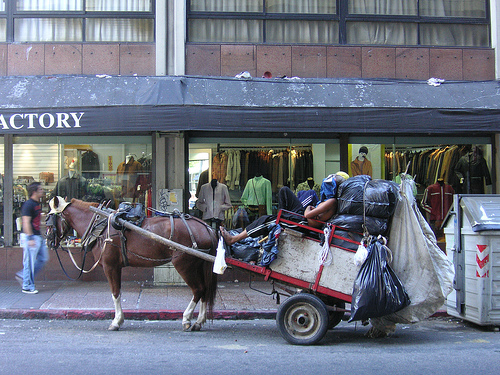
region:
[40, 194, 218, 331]
brown and white horse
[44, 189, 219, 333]
brown horse carrying a wheelbarrow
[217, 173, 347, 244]
man sleeping on a wheelbarrow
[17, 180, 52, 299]
man walking on sidewalk wearing blue t-shirt and blue jeans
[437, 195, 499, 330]
large store in the back big gray garbage can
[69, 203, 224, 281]
reins of a horse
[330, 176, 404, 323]
black bags on a red and white wheelbarrow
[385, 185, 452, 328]
big white bag on wheelbarrow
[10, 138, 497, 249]
a bunch of clothes in the shop window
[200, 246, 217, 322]
large black hairy tail of horse carrying a wheelbarrow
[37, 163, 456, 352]
A horse pulling a white cart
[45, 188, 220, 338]
Brown horse that is wearing gear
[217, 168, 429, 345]
Man resting in two wheel cart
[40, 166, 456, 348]
Horse pulling two wheeled white and red cart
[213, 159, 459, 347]
Man resting on a packed cart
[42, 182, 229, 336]
Brown horse with white stockings stopped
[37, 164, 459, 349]
Horse pulled cart stopped on road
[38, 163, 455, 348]
Horse drawn red and white cart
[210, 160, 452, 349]
Man resting on bags stacked in cart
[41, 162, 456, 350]
Horse drawn cart with man resting in the back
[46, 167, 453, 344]
stationary horse and buggy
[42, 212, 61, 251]
Horse blinders to restrict horse vision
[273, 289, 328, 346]
Rubber tire wheel on red cart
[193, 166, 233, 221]
Purple jacket on headless black manikin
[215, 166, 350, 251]
Man snoozing on cart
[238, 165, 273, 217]
Teal green shirt on black manikin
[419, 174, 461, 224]
White striped red jacket on black manikin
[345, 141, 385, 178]
Apparel store advertisement, black hat and orange jacket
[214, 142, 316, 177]
Rack of jackets in store window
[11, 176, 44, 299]
Man walking by clothing store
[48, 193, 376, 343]
A horse attached to a red and white cart.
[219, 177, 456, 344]
A cart filled with plastic bags.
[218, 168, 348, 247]
A man resting on the cart.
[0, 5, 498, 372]
Horse drawn cart in front of a business.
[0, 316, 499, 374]
An asphalt paved road.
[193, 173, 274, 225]
Jackets on headless mannequins.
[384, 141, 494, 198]
Jackets hanging on a rack inside of the store.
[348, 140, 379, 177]
Poster with a man wearing a hat on the window.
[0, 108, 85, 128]
Business name in white letters.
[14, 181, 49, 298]
A man wearing blue jeans standing on the sidewalk.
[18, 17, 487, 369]
a cart parked on a street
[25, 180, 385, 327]
a horse drawn car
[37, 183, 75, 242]
the horse is wearing a hat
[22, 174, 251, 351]
the horse is brown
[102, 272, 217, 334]
the horse has on white sox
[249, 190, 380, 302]
a white and red cart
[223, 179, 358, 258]
the driver is relaxing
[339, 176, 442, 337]
a pile of bags on the cart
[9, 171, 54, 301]
this guy is walking through the area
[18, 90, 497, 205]
this is a business next to the cart